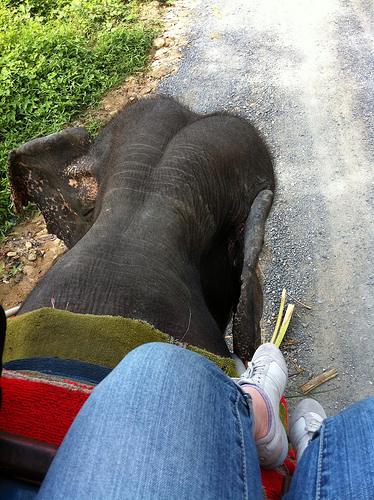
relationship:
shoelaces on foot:
[244, 364, 265, 379] [239, 342, 288, 471]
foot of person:
[239, 342, 288, 471] [34, 343, 373, 499]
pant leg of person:
[36, 341, 262, 499] [34, 343, 373, 499]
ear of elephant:
[7, 126, 96, 251] [8, 96, 276, 363]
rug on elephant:
[0, 307, 295, 500] [8, 96, 276, 363]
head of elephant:
[95, 96, 276, 331] [8, 96, 276, 363]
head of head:
[95, 96, 276, 264] [95, 96, 276, 331]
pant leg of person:
[284, 395, 373, 499] [34, 343, 373, 499]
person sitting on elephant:
[34, 343, 373, 499] [8, 96, 276, 363]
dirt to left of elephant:
[2, 0, 187, 317] [8, 96, 276, 363]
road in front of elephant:
[151, 1, 373, 424] [8, 96, 276, 363]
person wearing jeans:
[34, 343, 373, 499] [35, 343, 373, 499]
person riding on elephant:
[34, 343, 373, 499] [8, 96, 276, 363]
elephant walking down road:
[8, 96, 276, 363] [151, 1, 373, 424]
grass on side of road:
[0, 0, 168, 239] [151, 1, 373, 424]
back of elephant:
[14, 248, 231, 357] [8, 96, 276, 363]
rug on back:
[0, 307, 295, 500] [14, 248, 231, 357]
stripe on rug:
[0, 371, 94, 448] [0, 307, 295, 500]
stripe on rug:
[2, 307, 241, 378] [0, 307, 295, 500]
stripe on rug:
[1, 358, 112, 385] [0, 307, 295, 500]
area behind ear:
[63, 154, 97, 204] [7, 126, 96, 251]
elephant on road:
[8, 96, 276, 363] [151, 1, 373, 424]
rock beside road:
[152, 38, 164, 47] [151, 1, 373, 424]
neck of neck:
[45, 183, 219, 270] [45, 183, 219, 270]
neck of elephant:
[45, 183, 219, 270] [8, 96, 276, 363]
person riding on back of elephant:
[34, 343, 373, 499] [8, 96, 276, 363]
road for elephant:
[151, 1, 373, 424] [8, 96, 276, 363]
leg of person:
[34, 342, 270, 499] [34, 343, 373, 499]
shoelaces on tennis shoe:
[244, 364, 265, 379] [236, 342, 288, 470]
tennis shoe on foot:
[236, 342, 288, 470] [239, 342, 288, 471]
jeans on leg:
[35, 343, 373, 499] [34, 342, 270, 499]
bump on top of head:
[112, 96, 176, 152] [95, 96, 276, 331]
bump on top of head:
[185, 113, 269, 174] [95, 96, 276, 331]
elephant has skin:
[8, 96, 276, 363] [7, 95, 277, 369]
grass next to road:
[0, 0, 168, 239] [151, 1, 373, 424]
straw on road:
[269, 287, 294, 346] [151, 1, 373, 424]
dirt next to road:
[2, 0, 187, 317] [151, 1, 373, 424]